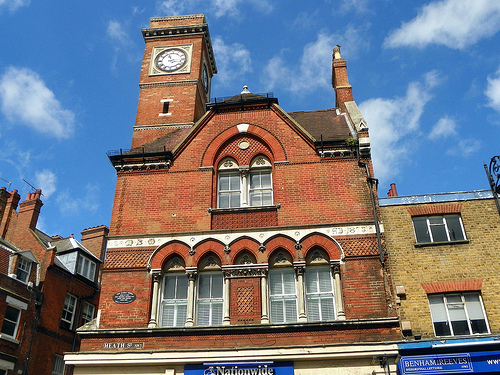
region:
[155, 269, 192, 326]
a window on a building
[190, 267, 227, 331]
a window on a building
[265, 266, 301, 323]
a window on a building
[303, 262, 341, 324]
a window on a building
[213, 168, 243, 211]
a window on a building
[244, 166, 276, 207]
a window on a building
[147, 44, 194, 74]
a clock on a brick tower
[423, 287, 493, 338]
a window on a building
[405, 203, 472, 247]
a window on a building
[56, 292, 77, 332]
a window on a building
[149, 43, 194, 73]
clock is on front of building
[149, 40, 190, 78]
clock is on top of building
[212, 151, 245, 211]
window is on front of building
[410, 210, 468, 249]
window is on front of building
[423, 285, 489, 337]
window is on front of building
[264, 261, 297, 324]
window is on front of building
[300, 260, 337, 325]
window is on front of building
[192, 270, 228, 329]
window is on front of building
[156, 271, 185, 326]
window is on front of building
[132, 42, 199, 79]
this is a clock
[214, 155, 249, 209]
this is a window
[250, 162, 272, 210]
this is a window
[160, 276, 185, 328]
this is a window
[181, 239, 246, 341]
this is a window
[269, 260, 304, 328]
this is a window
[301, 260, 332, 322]
this is a window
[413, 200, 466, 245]
this is a window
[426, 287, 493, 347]
this is a window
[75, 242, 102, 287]
this is a window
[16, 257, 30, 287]
this is a window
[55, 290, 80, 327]
this is a window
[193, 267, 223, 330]
this is a window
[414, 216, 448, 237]
a window on the building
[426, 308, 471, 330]
a window on the building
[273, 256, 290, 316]
a window on the building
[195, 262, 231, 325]
a window on the building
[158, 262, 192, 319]
a window on the building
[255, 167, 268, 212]
a window on the building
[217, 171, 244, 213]
a window on the building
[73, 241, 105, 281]
a window on the building